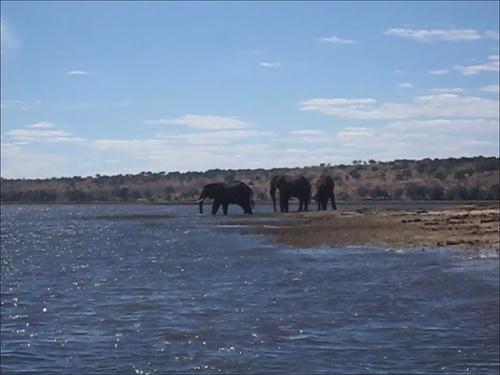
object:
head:
[194, 183, 213, 203]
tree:
[405, 185, 427, 201]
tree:
[421, 182, 443, 201]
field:
[0, 154, 500, 204]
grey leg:
[283, 189, 291, 209]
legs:
[210, 200, 220, 214]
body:
[210, 179, 253, 215]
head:
[268, 174, 282, 190]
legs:
[297, 197, 303, 212]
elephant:
[268, 173, 312, 212]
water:
[0, 203, 500, 374]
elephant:
[313, 172, 338, 211]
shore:
[214, 201, 499, 250]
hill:
[2, 154, 499, 204]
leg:
[223, 198, 231, 212]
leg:
[240, 203, 251, 214]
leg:
[316, 197, 322, 212]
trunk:
[197, 195, 205, 212]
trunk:
[268, 184, 278, 212]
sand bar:
[195, 203, 499, 249]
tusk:
[192, 197, 207, 204]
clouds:
[256, 61, 278, 70]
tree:
[452, 170, 463, 182]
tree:
[392, 172, 403, 181]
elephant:
[194, 180, 255, 217]